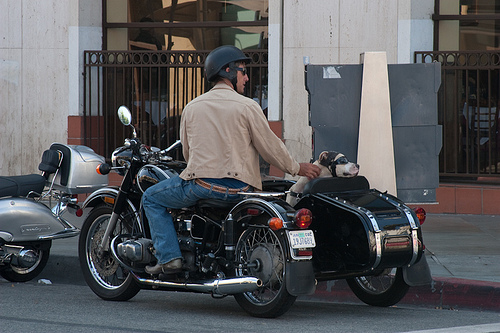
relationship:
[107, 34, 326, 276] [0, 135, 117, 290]
man on motorcycle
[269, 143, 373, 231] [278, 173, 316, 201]
dog in strap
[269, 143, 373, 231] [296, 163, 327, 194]
dog has shoulder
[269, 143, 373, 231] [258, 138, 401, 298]
dog in car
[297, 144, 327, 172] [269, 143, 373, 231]
hand on dog